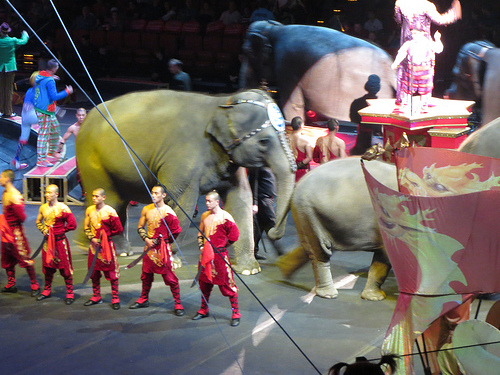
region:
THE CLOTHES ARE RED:
[139, 215, 191, 307]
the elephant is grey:
[69, 97, 286, 269]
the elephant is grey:
[293, 166, 406, 302]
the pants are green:
[35, 117, 65, 154]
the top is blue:
[28, 77, 66, 106]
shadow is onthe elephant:
[344, 69, 389, 114]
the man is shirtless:
[66, 109, 97, 144]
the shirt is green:
[2, 33, 28, 69]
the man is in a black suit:
[168, 69, 196, 92]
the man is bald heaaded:
[31, 184, 78, 299]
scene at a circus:
[18, 9, 488, 373]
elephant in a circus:
[81, 79, 315, 257]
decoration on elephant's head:
[228, 87, 299, 172]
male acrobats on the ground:
[2, 163, 282, 323]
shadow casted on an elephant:
[347, 65, 382, 143]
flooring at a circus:
[31, 323, 233, 369]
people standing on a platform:
[395, 0, 450, 100]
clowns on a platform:
[16, 45, 78, 165]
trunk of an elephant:
[270, 150, 295, 240]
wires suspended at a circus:
[55, 68, 160, 185]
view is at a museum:
[87, 35, 404, 370]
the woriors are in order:
[21, 188, 260, 319]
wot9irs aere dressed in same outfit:
[15, 165, 271, 372]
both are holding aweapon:
[111, 230, 264, 332]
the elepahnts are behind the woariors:
[95, 51, 462, 312]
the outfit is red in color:
[178, 245, 246, 325]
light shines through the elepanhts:
[310, 62, 435, 182]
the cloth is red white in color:
[340, 170, 486, 357]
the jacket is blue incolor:
[28, 71, 83, 109]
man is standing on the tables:
[7, 92, 105, 189]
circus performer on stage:
[0, 167, 42, 296]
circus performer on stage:
[29, 183, 76, 304]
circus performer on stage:
[82, 188, 124, 309]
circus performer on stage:
[123, 182, 186, 316]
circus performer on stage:
[186, 190, 241, 325]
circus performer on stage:
[312, 116, 346, 168]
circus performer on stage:
[284, 117, 313, 182]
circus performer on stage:
[55, 104, 89, 203]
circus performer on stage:
[33, 58, 71, 169]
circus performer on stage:
[11, 71, 42, 171]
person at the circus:
[189, 179, 249, 330]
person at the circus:
[127, 181, 184, 316]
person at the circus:
[82, 179, 122, 317]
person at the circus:
[35, 182, 87, 316]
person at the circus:
[0, 166, 42, 293]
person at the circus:
[32, 60, 64, 159]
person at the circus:
[315, 120, 344, 176]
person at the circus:
[276, 114, 308, 164]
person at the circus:
[394, 0, 445, 107]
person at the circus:
[0, 12, 16, 107]